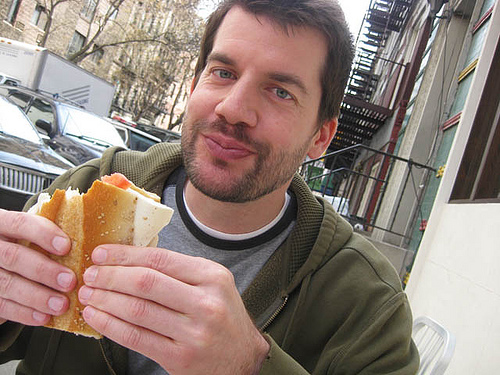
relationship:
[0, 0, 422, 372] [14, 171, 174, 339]
man holds bread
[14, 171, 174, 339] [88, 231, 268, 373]
bread in hand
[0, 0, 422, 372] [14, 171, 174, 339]
man holding bread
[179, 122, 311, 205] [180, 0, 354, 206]
goatee on mans face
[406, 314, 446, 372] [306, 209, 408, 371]
chair on sidewalk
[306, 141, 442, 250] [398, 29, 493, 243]
railing near door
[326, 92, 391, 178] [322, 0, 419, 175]
platform of fire escape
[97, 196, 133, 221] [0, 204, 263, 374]
bread in hands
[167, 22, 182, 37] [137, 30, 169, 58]
leaves on branches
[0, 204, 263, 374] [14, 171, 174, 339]
hands holding bread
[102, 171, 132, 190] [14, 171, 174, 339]
meat inside bread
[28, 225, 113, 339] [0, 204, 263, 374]
nails on hands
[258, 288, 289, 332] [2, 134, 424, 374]
zipper on jacket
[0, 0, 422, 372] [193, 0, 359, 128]
man has hair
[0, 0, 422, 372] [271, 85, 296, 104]
man has eye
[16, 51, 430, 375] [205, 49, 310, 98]
man has eye brows